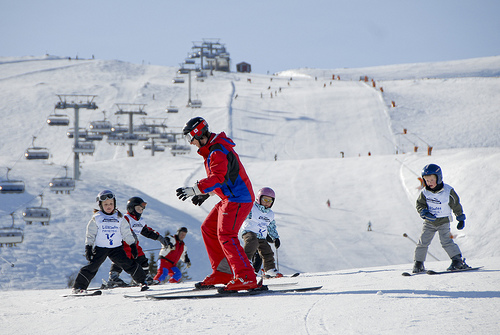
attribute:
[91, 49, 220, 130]
lift — chairs, empty, long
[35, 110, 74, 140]
chair — hanging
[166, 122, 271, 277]
man — wearing, skiing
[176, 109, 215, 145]
helmet — blue, worn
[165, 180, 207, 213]
glove — white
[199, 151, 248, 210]
coat — blue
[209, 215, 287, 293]
pants — striped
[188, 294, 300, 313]
ski — black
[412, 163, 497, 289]
child — standing, skiing, here, wearing, behind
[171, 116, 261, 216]
instructor — skiin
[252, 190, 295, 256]
skier — small, young, here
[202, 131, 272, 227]
jacket — blue, red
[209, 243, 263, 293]
boot — red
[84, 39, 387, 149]
mountain — snow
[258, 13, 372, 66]
sky — cloudless, blue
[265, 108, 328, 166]
ground — covered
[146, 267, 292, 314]
skis — worn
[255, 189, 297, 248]
girl — wearing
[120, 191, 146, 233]
kid — wearing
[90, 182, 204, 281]
people — riding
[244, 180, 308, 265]
person — here, wearing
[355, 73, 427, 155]
barrels — orangw